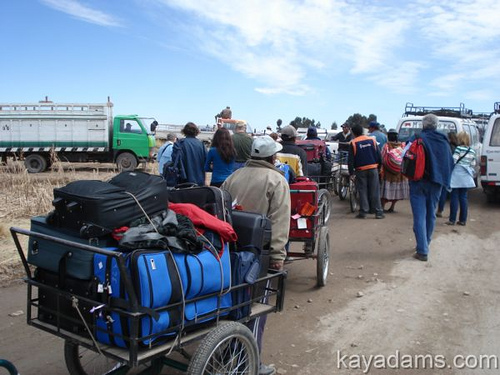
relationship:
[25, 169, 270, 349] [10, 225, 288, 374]
luggage in cart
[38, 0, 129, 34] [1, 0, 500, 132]
cloud in sky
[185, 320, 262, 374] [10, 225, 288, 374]
tire under wagon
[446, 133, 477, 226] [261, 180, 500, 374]
person walking road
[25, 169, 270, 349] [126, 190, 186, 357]
luggage strapped down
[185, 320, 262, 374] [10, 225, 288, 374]
wheel on cart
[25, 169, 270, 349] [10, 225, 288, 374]
luggage on cart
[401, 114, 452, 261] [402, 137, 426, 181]
man carrying backpack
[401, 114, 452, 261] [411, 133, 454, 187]
man in jacket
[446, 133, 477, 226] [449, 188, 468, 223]
person wearing jeans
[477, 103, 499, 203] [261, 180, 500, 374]
van on road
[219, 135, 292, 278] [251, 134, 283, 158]
man wearing cap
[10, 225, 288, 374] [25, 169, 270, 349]
cart carrying luggage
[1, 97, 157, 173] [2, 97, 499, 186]
truck in background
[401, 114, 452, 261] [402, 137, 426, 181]
man carrying bag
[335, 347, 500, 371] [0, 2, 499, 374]
mark on image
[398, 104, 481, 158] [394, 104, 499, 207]
car in group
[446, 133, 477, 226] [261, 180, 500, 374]
person on road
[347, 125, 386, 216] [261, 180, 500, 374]
person on road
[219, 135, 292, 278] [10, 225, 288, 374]
man pulling cart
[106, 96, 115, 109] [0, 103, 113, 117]
man on roof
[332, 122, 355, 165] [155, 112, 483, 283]
man facing crowd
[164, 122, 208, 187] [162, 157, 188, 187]
woman carrying bag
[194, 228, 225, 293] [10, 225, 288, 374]
cord on cart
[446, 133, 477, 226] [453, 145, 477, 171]
person` in top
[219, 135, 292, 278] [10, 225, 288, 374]
man pulls cart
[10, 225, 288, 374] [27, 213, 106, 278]
cart has suitcase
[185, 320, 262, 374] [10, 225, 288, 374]
tire supports cart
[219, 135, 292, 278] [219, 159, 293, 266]
man wearing jacket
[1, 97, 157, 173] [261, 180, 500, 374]
truck on side of road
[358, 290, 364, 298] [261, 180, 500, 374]
stone along road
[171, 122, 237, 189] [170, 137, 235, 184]
couple wearing shirts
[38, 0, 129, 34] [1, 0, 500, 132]
cloud floats in sky